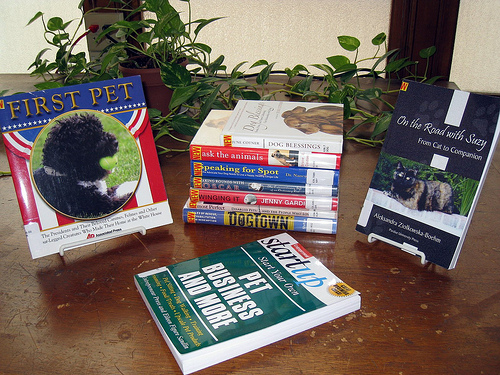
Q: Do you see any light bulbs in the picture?
A: No, there are no light bulbs.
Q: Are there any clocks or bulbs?
A: No, there are no bulbs or clocks.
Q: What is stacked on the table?
A: The book is stacked on the table.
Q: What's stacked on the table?
A: The book is stacked on the table.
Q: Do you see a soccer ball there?
A: No, there are no soccer balls.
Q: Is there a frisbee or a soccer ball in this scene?
A: No, there are no soccer balls or frisbees.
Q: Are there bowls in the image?
A: No, there are no bowls.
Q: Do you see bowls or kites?
A: No, there are no bowls or kites.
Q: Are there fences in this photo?
A: No, there are no fences.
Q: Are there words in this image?
A: Yes, there are words.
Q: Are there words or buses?
A: Yes, there are words.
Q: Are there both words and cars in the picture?
A: No, there are words but no cars.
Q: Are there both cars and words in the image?
A: No, there are words but no cars.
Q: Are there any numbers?
A: No, there are no numbers.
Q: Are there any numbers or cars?
A: No, there are no numbers or cars.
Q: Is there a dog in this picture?
A: Yes, there is a dog.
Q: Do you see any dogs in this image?
A: Yes, there is a dog.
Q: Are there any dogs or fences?
A: Yes, there is a dog.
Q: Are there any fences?
A: No, there are no fences.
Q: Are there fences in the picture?
A: No, there are no fences.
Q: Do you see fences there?
A: No, there are no fences.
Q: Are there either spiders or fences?
A: No, there are no fences or spiders.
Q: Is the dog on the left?
A: Yes, the dog is on the left of the image.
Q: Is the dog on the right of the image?
A: No, the dog is on the left of the image.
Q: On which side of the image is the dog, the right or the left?
A: The dog is on the left of the image.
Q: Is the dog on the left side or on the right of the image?
A: The dog is on the left of the image.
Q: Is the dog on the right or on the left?
A: The dog is on the left of the image.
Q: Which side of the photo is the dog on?
A: The dog is on the left of the image.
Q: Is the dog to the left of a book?
A: Yes, the dog is to the left of a book.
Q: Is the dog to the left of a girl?
A: No, the dog is to the left of a book.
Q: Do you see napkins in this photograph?
A: No, there are no napkins.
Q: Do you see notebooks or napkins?
A: No, there are no napkins or notebooks.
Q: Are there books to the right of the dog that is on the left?
A: Yes, there is a book to the right of the dog.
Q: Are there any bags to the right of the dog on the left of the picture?
A: No, there is a book to the right of the dog.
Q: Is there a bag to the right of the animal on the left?
A: No, there is a book to the right of the dog.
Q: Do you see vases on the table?
A: No, there is a book on the table.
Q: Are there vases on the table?
A: No, there is a book on the table.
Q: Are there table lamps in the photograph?
A: No, there are no table lamps.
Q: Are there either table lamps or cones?
A: No, there are no table lamps or cones.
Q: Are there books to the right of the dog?
A: Yes, there is a book to the right of the dog.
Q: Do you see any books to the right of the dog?
A: Yes, there is a book to the right of the dog.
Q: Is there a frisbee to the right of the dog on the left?
A: No, there is a book to the right of the dog.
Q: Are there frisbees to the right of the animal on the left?
A: No, there is a book to the right of the dog.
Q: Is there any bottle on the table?
A: No, there is a book on the table.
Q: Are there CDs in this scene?
A: No, there are no cds.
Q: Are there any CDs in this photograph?
A: No, there are no cds.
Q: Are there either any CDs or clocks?
A: No, there are no CDs or clocks.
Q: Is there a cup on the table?
A: No, there is a book on the table.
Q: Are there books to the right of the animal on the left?
A: Yes, there is a book to the right of the dog.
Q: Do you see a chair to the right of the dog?
A: No, there is a book to the right of the dog.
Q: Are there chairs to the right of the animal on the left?
A: No, there is a book to the right of the dog.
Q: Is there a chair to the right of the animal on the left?
A: No, there is a book to the right of the dog.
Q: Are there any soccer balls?
A: No, there are no soccer balls.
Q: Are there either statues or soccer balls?
A: No, there are no soccer balls or statues.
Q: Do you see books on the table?
A: Yes, there is a book on the table.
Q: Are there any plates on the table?
A: No, there is a book on the table.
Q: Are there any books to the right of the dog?
A: Yes, there is a book to the right of the dog.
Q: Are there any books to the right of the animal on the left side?
A: Yes, there is a book to the right of the dog.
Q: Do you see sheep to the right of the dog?
A: No, there is a book to the right of the dog.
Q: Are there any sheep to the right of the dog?
A: No, there is a book to the right of the dog.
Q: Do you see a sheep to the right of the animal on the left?
A: No, there is a book to the right of the dog.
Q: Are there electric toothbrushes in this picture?
A: No, there are no electric toothbrushes.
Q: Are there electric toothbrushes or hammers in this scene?
A: No, there are no electric toothbrushes or hammers.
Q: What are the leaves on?
A: The leaves are on the table.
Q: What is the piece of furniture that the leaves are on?
A: The piece of furniture is a table.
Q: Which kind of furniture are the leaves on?
A: The leaves are on the table.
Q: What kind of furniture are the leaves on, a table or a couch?
A: The leaves are on a table.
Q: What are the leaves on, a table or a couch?
A: The leaves are on a table.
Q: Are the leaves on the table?
A: Yes, the leaves are on the table.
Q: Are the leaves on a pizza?
A: No, the leaves are on the table.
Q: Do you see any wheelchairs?
A: No, there are no wheelchairs.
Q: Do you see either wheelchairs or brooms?
A: No, there are no wheelchairs or brooms.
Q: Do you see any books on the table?
A: Yes, there is a book on the table.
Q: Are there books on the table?
A: Yes, there is a book on the table.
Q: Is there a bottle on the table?
A: No, there is a book on the table.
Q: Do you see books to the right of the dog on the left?
A: Yes, there is a book to the right of the dog.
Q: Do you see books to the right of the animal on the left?
A: Yes, there is a book to the right of the dog.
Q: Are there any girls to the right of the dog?
A: No, there is a book to the right of the dog.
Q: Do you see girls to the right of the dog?
A: No, there is a book to the right of the dog.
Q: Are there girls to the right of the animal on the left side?
A: No, there is a book to the right of the dog.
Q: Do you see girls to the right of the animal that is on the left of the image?
A: No, there is a book to the right of the dog.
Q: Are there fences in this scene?
A: No, there are no fences.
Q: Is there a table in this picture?
A: Yes, there is a table.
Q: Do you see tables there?
A: Yes, there is a table.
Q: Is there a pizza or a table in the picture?
A: Yes, there is a table.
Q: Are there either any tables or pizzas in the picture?
A: Yes, there is a table.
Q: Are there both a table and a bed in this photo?
A: No, there is a table but no beds.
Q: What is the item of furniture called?
A: The piece of furniture is a table.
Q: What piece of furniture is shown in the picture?
A: The piece of furniture is a table.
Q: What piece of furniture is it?
A: The piece of furniture is a table.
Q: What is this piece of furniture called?
A: This is a table.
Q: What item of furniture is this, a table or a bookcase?
A: This is a table.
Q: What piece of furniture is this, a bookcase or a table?
A: This is a table.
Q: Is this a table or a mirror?
A: This is a table.